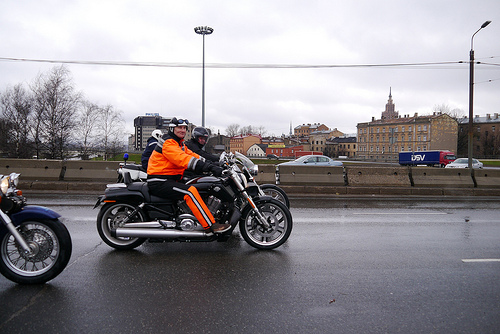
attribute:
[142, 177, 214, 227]
pants — black, orange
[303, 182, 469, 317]
road — grey, wet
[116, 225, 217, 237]
pipe — chrome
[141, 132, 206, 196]
jacket — orange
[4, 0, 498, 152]
sky — grey, cloudy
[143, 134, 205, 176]
jacket — orange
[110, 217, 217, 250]
pipe — silver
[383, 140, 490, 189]
truck — blue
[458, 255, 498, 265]
line — white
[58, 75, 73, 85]
branch — bare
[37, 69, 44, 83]
branch — bare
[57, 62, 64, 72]
branch — bare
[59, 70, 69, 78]
branch — bare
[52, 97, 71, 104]
branch — bare